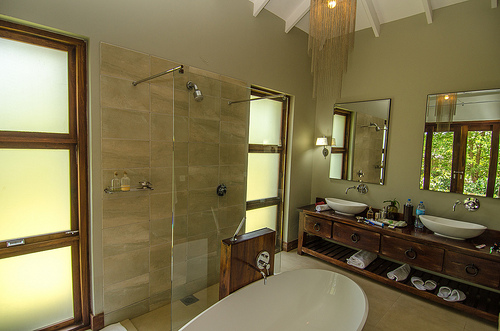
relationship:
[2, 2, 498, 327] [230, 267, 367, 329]
bathroom has tub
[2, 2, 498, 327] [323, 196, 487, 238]
bathroom has sinks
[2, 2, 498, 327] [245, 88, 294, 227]
bathroom has window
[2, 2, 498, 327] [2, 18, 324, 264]
bathroom has wall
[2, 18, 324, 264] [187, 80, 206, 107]
wall has shower head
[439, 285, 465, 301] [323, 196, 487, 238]
slippers under sinks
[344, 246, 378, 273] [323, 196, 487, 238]
towels under sinks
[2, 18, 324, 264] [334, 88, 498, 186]
wall has mirrors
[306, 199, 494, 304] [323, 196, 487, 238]
table has sinks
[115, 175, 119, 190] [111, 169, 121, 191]
bottle of shampoo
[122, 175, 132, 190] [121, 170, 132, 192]
bottle of conditioner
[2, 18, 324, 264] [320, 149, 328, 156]
wall has sconce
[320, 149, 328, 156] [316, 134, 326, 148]
sconce has shade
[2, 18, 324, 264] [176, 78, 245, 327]
wall has glass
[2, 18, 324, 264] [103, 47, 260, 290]
wall has shower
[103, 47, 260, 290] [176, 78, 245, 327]
shower has glass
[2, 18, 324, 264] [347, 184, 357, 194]
wall has faucet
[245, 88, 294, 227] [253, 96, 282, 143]
window has panels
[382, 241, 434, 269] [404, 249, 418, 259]
drawer has handle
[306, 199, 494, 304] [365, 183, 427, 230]
vanity has toiletries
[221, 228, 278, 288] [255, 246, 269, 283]
wooden piece has faucet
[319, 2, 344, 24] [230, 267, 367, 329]
light above tub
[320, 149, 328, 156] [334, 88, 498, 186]
sconce near mirrors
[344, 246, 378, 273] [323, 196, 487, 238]
towels under vanity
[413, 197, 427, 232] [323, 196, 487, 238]
bottle near sinks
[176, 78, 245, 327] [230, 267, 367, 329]
glass near tub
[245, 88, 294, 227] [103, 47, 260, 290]
window near shower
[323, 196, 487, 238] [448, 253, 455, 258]
sinks on wood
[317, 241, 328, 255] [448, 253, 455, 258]
shelf under wood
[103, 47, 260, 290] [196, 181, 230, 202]
shower has fixtures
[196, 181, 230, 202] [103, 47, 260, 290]
fixtures inside shower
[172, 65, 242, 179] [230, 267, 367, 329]
wall beside tub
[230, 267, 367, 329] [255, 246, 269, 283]
tub has faucet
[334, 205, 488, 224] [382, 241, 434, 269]
vanity has drawer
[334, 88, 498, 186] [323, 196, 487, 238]
mirrors above sinks